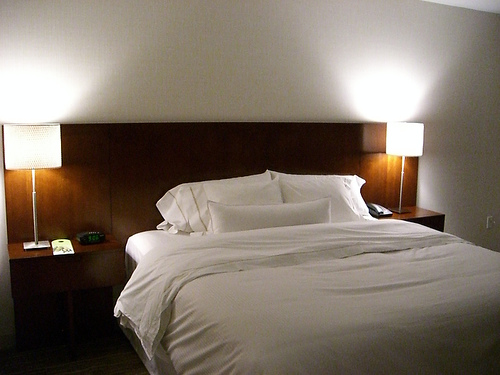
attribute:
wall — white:
[0, 1, 498, 254]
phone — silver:
[367, 194, 387, 221]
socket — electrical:
[484, 214, 494, 231]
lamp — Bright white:
[0, 122, 62, 249]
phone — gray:
[363, 199, 394, 221]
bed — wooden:
[87, 122, 488, 342]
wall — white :
[6, 10, 487, 134]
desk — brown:
[2, 227, 140, 373]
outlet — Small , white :
[484, 214, 495, 231]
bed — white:
[117, 174, 499, 374]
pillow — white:
[208, 198, 331, 238]